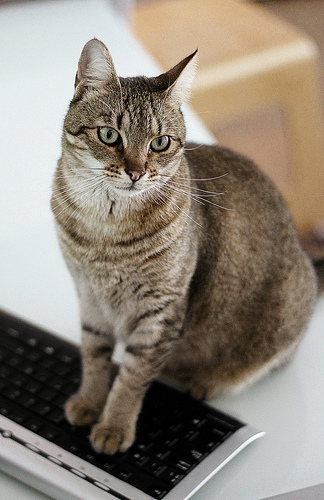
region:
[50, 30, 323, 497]
A grey cat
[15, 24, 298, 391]
A grey cat with a few small stripes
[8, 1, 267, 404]
A grey cat with small black stripes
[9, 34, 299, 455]
A cat with its paws on a keyboard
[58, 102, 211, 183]
A cat with blue-green eyes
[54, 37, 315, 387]
A cat sitting on a desk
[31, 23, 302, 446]
A cat sitting on a desk with its paws on a keyboard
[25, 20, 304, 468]
A cat resting its paws on a keyboard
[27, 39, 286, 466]
A grey cat on a white desk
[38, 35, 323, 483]
A cat with grey fur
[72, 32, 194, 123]
cat has light brown ears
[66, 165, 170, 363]
cat has brown stripes on body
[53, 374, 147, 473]
cat has brown paws on keyboard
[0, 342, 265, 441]
keyboard is silver and black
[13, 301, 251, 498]
keyboard is on white table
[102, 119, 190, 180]
cat has olive colored eyes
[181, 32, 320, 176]
brown floor is behind cat and table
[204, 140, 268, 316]
cat has dark brown fur on body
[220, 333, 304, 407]
cat has light colored feet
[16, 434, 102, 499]
grey buttons on top of keyboard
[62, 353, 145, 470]
cat has paws on keyboard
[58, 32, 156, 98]
cat has light brown and pointed ears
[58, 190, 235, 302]
cat has dark brown stripes on neck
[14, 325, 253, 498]
keyboard has silver frame and black keys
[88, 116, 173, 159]
cat has round green eyes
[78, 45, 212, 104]
cat's ears are pointing backward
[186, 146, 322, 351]
cat has dark brown fur on back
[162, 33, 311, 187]
floor under table and behind cat is brown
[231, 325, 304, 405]
cat has light brown rear paws under body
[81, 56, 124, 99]
Inside of cat's ear is white.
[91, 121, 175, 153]
Cat has green eyes.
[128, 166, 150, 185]
End of cat's nose is pink.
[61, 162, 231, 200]
Cat has white whiskers.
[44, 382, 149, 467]
Cat has brown paws.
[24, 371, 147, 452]
Cat is standing on keyboard.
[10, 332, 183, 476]
Buttons on keyboard are black.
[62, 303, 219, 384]
Cat has stripes on legs.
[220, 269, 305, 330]
Cat has gray fur on backside.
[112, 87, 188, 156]
Cat has black stripes on head.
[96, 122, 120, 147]
grayish blue cat eye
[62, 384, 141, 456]
Cat paws on a key board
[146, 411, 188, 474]
Black keyboard keys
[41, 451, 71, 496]
Silver and black keyboard trim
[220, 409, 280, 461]
A keyboard on a table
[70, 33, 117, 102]
The ear of a cat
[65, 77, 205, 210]
The face of a cat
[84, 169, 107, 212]
White cat whiskers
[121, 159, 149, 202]
A cats nose and mouth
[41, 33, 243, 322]
A beautiful gray, black and white cat